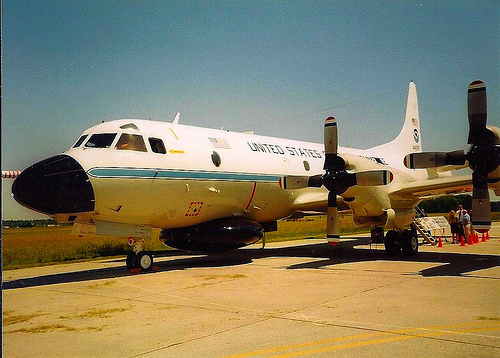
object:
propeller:
[277, 116, 393, 247]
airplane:
[11, 79, 500, 272]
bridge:
[412, 221, 436, 246]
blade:
[324, 116, 339, 168]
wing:
[293, 167, 492, 231]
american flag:
[208, 137, 233, 150]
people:
[447, 208, 460, 243]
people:
[456, 203, 466, 241]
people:
[461, 210, 471, 244]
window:
[73, 132, 118, 148]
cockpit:
[69, 118, 168, 165]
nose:
[9, 154, 95, 215]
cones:
[459, 236, 465, 247]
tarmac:
[1, 222, 500, 356]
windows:
[211, 151, 221, 167]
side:
[99, 158, 269, 216]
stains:
[1, 305, 129, 332]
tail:
[368, 82, 429, 182]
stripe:
[88, 167, 280, 183]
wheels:
[126, 251, 153, 271]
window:
[115, 133, 147, 153]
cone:
[436, 237, 443, 247]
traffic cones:
[468, 232, 474, 245]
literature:
[419, 216, 449, 231]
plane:
[126, 297, 187, 333]